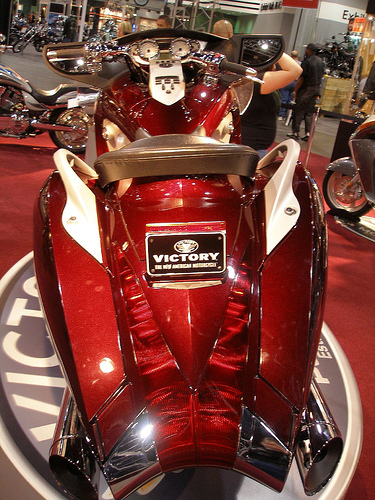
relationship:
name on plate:
[151, 252, 223, 265] [145, 222, 231, 287]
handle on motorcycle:
[214, 55, 264, 88] [32, 19, 329, 480]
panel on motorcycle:
[130, 36, 208, 63] [32, 19, 329, 480]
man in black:
[292, 38, 326, 147] [298, 118, 299, 126]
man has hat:
[292, 38, 326, 147] [308, 42, 324, 51]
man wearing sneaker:
[292, 38, 326, 147] [290, 134, 297, 141]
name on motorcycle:
[151, 252, 223, 265] [32, 19, 329, 480]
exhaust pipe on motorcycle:
[298, 418, 344, 499] [32, 19, 329, 480]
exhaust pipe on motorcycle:
[43, 405, 104, 498] [32, 19, 329, 480]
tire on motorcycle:
[52, 111, 88, 151] [3, 68, 91, 154]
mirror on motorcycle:
[41, 41, 94, 75] [32, 19, 329, 480]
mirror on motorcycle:
[240, 31, 293, 67] [32, 19, 329, 480]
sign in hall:
[322, 2, 365, 24] [21, 4, 358, 56]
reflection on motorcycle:
[128, 187, 228, 214] [32, 19, 329, 480]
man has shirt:
[292, 38, 326, 147] [304, 59, 320, 86]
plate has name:
[145, 222, 231, 287] [151, 252, 223, 265]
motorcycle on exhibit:
[32, 19, 329, 480] [6, 288, 59, 411]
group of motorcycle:
[11, 13, 34, 35] [12, 27, 49, 52]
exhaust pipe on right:
[298, 418, 344, 499] [317, 137, 340, 177]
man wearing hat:
[213, 15, 241, 39] [308, 42, 324, 51]